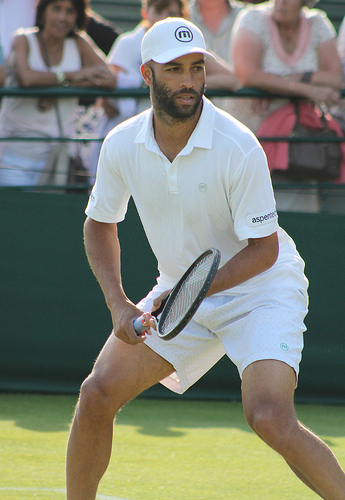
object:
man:
[64, 14, 345, 500]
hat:
[139, 15, 218, 66]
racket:
[132, 247, 222, 342]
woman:
[0, 0, 118, 193]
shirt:
[82, 94, 299, 294]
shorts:
[134, 257, 311, 396]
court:
[142, 426, 232, 465]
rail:
[25, 85, 65, 101]